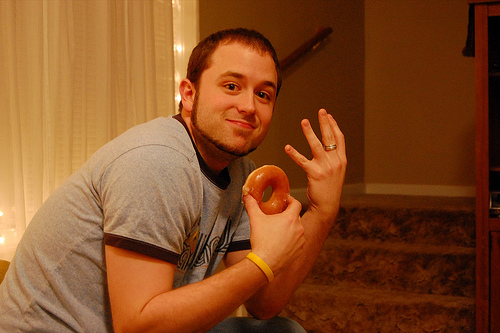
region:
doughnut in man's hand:
[242, 165, 297, 217]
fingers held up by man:
[282, 103, 345, 183]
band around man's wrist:
[246, 249, 274, 283]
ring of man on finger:
[322, 143, 339, 151]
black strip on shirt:
[98, 230, 183, 264]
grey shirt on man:
[2, 115, 233, 325]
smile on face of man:
[222, 102, 262, 133]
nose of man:
[237, 91, 254, 113]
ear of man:
[177, 80, 199, 108]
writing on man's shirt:
[184, 222, 221, 268]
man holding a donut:
[0, 36, 398, 306]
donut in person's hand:
[240, 163, 297, 216]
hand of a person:
[272, 104, 357, 184]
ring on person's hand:
[325, 141, 334, 153]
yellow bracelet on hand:
[238, 240, 286, 291]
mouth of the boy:
[218, 113, 250, 132]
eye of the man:
[220, 78, 242, 99]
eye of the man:
[252, 88, 284, 108]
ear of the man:
[179, 77, 196, 118]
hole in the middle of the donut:
[257, 180, 277, 203]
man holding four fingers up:
[10, 29, 354, 322]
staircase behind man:
[276, 178, 473, 323]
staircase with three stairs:
[261, 187, 471, 322]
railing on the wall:
[278, 34, 360, 87]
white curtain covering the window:
[4, 38, 201, 243]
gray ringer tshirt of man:
[5, 115, 255, 326]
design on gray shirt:
[185, 218, 240, 273]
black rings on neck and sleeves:
[102, 114, 257, 266]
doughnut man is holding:
[240, 160, 295, 222]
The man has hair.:
[172, 20, 288, 162]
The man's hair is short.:
[174, 18, 286, 167]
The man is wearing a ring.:
[178, 22, 352, 323]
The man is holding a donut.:
[90, 18, 348, 331]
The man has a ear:
[176, 28, 247, 159]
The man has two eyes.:
[176, 25, 284, 161]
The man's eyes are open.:
[175, 22, 285, 159]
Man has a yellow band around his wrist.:
[153, 22, 348, 332]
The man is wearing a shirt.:
[0, 24, 352, 331]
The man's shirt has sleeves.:
[0, 21, 351, 331]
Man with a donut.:
[36, 11, 406, 332]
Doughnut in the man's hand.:
[222, 131, 354, 276]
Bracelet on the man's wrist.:
[239, 246, 280, 307]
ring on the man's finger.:
[282, 103, 416, 210]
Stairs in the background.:
[313, 154, 440, 329]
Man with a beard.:
[163, 20, 352, 189]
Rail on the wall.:
[266, 27, 383, 104]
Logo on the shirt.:
[169, 168, 219, 320]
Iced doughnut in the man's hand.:
[226, 162, 322, 232]